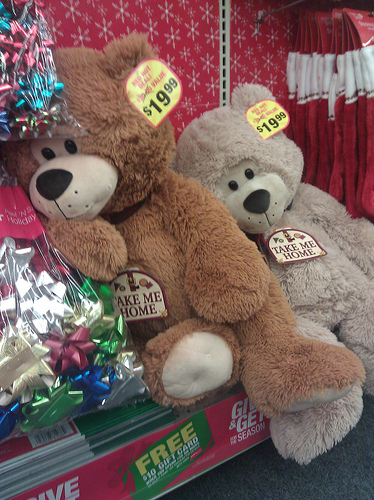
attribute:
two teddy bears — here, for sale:
[11, 27, 370, 458]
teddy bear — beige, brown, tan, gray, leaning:
[158, 74, 373, 463]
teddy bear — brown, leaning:
[11, 34, 369, 430]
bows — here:
[12, 261, 108, 388]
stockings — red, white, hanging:
[276, 7, 372, 222]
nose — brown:
[28, 163, 83, 208]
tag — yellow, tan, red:
[237, 95, 298, 146]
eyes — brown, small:
[226, 164, 258, 196]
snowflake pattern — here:
[62, 4, 292, 91]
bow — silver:
[6, 268, 77, 340]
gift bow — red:
[33, 320, 102, 378]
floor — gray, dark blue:
[186, 407, 372, 498]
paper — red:
[70, 3, 298, 107]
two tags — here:
[113, 52, 303, 157]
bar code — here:
[31, 420, 69, 448]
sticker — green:
[124, 408, 222, 496]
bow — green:
[25, 374, 89, 435]